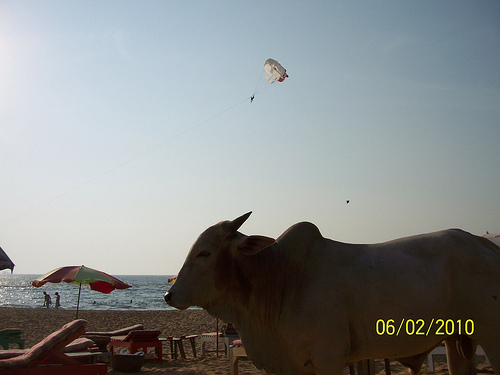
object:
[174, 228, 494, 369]
bull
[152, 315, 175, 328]
beach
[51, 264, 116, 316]
umbrella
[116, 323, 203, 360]
benches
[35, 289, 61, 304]
couple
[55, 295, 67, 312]
people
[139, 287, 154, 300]
water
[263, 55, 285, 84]
parasail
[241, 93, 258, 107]
person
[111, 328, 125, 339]
cushions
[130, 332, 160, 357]
lounger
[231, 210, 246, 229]
horn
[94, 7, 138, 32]
sky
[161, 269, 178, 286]
objects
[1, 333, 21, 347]
basket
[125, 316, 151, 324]
sand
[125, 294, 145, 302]
ocean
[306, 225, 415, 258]
hump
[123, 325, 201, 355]
furniture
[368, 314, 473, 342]
06/02/2010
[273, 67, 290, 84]
kite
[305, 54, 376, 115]
air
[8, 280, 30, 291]
sun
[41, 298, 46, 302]
hand